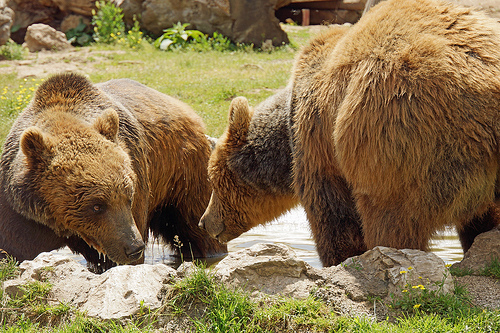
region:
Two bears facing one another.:
[28, 116, 413, 293]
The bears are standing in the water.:
[27, 95, 496, 298]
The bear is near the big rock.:
[221, 123, 481, 241]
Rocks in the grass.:
[13, 254, 421, 331]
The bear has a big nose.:
[71, 186, 188, 274]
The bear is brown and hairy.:
[253, 31, 459, 232]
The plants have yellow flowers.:
[91, 16, 139, 52]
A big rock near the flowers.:
[16, 12, 108, 74]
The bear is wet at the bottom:
[131, 181, 238, 276]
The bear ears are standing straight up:
[211, 68, 266, 146]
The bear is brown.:
[193, 15, 498, 245]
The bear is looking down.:
[185, 73, 356, 256]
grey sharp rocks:
[27, 247, 474, 331]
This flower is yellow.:
[397, 274, 430, 327]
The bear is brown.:
[5, 57, 222, 269]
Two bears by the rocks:
[8, 29, 498, 261]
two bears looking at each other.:
[25, 54, 427, 300]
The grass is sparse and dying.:
[114, 37, 282, 116]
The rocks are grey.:
[25, 235, 498, 307]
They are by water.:
[234, 207, 328, 287]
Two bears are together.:
[0, 0, 496, 282]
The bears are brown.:
[0, 0, 497, 280]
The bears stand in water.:
[0, 1, 498, 298]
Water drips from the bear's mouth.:
[54, 206, 171, 283]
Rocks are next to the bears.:
[0, 224, 492, 324]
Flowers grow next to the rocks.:
[374, 259, 448, 321]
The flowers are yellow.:
[361, 261, 454, 322]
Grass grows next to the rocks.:
[0, 278, 494, 331]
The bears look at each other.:
[30, 87, 332, 280]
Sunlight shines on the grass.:
[0, 4, 361, 146]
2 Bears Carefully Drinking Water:
[5, 4, 495, 331]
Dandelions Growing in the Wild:
[391, 257, 443, 324]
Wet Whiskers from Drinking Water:
[53, 178, 150, 276]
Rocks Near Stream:
[4, 229, 498, 328]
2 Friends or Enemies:
[7, 6, 493, 328]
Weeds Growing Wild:
[76, 3, 276, 64]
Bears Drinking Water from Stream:
[5, 5, 495, 326]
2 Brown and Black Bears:
[1, 6, 494, 327]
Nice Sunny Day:
[5, 5, 291, 70]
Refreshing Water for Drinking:
[14, 91, 474, 275]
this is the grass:
[220, 292, 250, 327]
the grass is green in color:
[206, 293, 243, 323]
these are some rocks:
[223, 245, 448, 314]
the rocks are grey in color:
[254, 242, 293, 293]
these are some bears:
[0, 75, 497, 252]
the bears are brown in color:
[334, 66, 399, 106]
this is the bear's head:
[191, 100, 278, 234]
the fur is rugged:
[356, 89, 467, 141]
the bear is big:
[202, 1, 499, 308]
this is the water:
[282, 216, 299, 239]